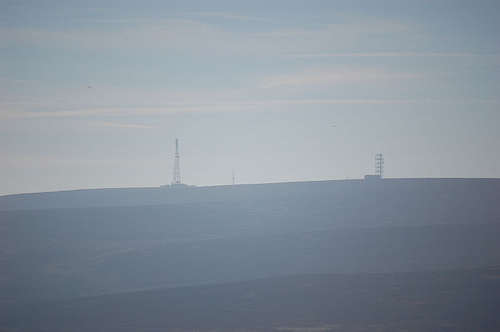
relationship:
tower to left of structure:
[171, 136, 182, 186] [231, 165, 236, 185]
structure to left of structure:
[231, 165, 236, 185] [363, 150, 386, 178]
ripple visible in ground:
[1, 190, 499, 214] [0, 177, 500, 332]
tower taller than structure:
[171, 136, 182, 186] [231, 165, 236, 185]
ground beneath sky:
[0, 177, 500, 332] [1, 2, 499, 196]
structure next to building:
[363, 150, 386, 178] [364, 173, 380, 181]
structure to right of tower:
[231, 165, 236, 185] [171, 136, 182, 186]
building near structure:
[364, 173, 380, 181] [363, 150, 386, 178]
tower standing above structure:
[171, 136, 182, 186] [231, 165, 236, 185]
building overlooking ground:
[364, 173, 380, 181] [0, 177, 500, 332]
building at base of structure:
[364, 173, 380, 181] [363, 150, 386, 178]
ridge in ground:
[4, 266, 499, 311] [0, 177, 500, 332]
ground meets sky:
[0, 177, 500, 332] [1, 2, 499, 196]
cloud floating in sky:
[2, 97, 500, 115] [1, 2, 499, 196]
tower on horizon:
[171, 136, 182, 186] [0, 177, 500, 200]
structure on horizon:
[231, 165, 236, 185] [0, 177, 500, 200]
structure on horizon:
[363, 150, 386, 178] [0, 177, 500, 200]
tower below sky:
[171, 136, 182, 186] [1, 2, 499, 196]